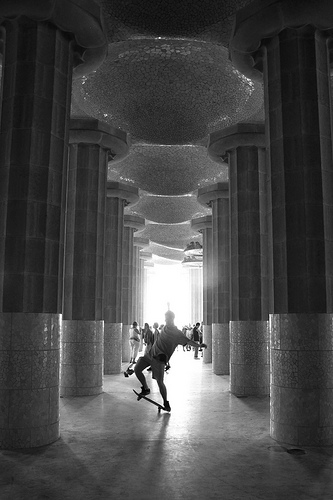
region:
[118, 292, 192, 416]
Skateboarder in a building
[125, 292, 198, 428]
Skater making tricks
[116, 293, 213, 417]
Skater has extended arms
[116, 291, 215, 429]
Skater wears shirt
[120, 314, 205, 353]
Many people behind skater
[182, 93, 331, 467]
Building has columns on the right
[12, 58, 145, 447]
Building has columns on the left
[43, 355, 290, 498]
Floor of building is made of granite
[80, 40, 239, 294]
Ceiling of building is cancave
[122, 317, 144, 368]
Woman wearing white outfit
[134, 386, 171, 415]
man riding skateboard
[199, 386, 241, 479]
long grey hallway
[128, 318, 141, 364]
woman dressed in black in background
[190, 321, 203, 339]
man in black shirt in background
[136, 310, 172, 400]
man in shirt and shorts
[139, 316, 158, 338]
people in the background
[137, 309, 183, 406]
man losing his balance on skateboard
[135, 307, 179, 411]
man is about to fall off skateboard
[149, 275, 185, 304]
light from the outside coming in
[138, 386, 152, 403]
man is wearing shoes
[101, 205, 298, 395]
The picture is black and white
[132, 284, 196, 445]
The man is skateboarding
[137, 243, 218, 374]
There is light in the background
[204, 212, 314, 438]
The poles are vertical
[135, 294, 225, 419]
There is a group of people in the background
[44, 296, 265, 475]
The building is stone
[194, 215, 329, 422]
The poles are round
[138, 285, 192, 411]
The man is wearing shorts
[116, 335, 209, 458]
The man is wearing black shoes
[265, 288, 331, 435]
The bottom of the poles are brick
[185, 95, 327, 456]
Columns of building are made of cement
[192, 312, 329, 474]
Columns of building are painted of white at the bottom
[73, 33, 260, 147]
Ceiling of building have concave designs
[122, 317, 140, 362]
Woman wearing white cloths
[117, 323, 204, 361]
People behind the skater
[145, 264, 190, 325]
Outdoor of building is sunny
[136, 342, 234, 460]
Light reflecting in the floor of building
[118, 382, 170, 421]
Skateboard is raised on left side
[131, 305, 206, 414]
a man is skating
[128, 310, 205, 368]
people in the background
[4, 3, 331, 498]
a picture of a building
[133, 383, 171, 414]
shoes that are black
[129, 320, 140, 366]
a woman in white is standing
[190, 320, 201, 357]
a man in black shirt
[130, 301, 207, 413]
a man's arms stretched out.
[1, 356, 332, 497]
the floor of a building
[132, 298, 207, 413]
a man in a shirt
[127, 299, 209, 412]
a man in shorts skating